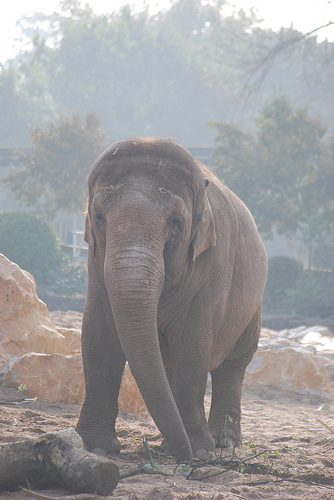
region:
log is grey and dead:
[0, 420, 119, 485]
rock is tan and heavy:
[248, 340, 324, 388]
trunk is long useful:
[113, 271, 187, 466]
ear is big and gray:
[184, 173, 212, 258]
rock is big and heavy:
[248, 343, 325, 401]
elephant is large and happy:
[74, 134, 262, 448]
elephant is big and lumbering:
[73, 137, 262, 454]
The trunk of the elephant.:
[103, 226, 194, 459]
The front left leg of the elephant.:
[81, 289, 117, 448]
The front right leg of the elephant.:
[163, 318, 206, 451]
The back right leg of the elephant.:
[211, 339, 237, 439]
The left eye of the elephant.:
[96, 213, 101, 223]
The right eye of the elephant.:
[167, 217, 181, 226]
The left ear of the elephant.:
[82, 186, 95, 253]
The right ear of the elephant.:
[196, 175, 212, 255]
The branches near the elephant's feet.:
[124, 429, 283, 493]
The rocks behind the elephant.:
[0, 249, 330, 417]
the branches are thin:
[157, 439, 240, 475]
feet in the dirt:
[84, 428, 246, 455]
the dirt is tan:
[251, 382, 315, 447]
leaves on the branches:
[222, 422, 273, 482]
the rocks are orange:
[0, 267, 91, 403]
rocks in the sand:
[254, 346, 327, 405]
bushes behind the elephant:
[4, 212, 332, 308]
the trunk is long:
[106, 236, 190, 463]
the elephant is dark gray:
[74, 141, 289, 423]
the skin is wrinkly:
[45, 154, 209, 342]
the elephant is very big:
[76, 171, 272, 421]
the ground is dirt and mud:
[88, 423, 293, 490]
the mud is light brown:
[166, 427, 249, 497]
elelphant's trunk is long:
[83, 145, 197, 468]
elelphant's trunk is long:
[90, 187, 203, 481]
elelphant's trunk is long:
[105, 208, 196, 475]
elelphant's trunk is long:
[91, 223, 206, 495]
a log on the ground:
[11, 410, 124, 498]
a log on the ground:
[6, 418, 120, 496]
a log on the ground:
[12, 416, 115, 495]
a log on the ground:
[12, 420, 134, 498]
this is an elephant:
[66, 119, 272, 461]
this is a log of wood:
[3, 428, 123, 496]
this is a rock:
[1, 255, 66, 385]